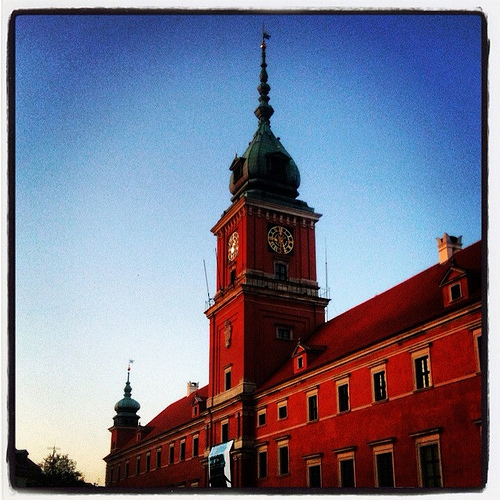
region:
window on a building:
[414, 435, 446, 487]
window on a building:
[373, 442, 398, 487]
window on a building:
[336, 450, 352, 492]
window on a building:
[306, 456, 318, 491]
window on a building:
[276, 436, 291, 475]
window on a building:
[257, 444, 271, 480]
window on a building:
[253, 405, 268, 425]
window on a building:
[276, 401, 290, 419]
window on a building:
[303, 385, 319, 420]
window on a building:
[332, 374, 355, 411]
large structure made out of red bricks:
[91, 26, 499, 496]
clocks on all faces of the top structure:
[213, 214, 320, 279]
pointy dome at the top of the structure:
[213, 21, 311, 209]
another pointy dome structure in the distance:
[108, 353, 146, 433]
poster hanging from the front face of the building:
[198, 436, 243, 492]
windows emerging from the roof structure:
[129, 269, 478, 446]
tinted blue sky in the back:
[3, 10, 485, 387]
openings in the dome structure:
[223, 153, 295, 185]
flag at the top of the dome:
[252, 23, 277, 55]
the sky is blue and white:
[41, 269, 188, 331]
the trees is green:
[42, 449, 84, 476]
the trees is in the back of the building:
[44, 435, 94, 485]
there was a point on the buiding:
[117, 343, 137, 409]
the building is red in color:
[155, 350, 412, 430]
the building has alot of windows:
[279, 362, 458, 397]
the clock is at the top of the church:
[264, 223, 308, 254]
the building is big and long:
[156, 382, 456, 467]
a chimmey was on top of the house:
[434, 241, 469, 263]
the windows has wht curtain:
[416, 362, 428, 389]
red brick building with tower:
[97, 20, 487, 485]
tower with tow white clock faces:
[200, 15, 327, 397]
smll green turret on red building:
[109, 357, 150, 440]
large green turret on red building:
[225, 20, 300, 196]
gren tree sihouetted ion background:
[38, 443, 87, 488]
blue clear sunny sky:
[30, 22, 480, 459]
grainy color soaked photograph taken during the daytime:
[20, 15, 485, 482]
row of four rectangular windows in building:
[304, 428, 452, 491]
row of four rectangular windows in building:
[290, 343, 449, 430]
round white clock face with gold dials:
[265, 219, 300, 258]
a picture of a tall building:
[159, 155, 429, 462]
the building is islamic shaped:
[76, 74, 466, 481]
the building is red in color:
[148, 362, 370, 497]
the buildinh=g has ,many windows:
[127, 360, 419, 472]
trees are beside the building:
[23, 416, 100, 498]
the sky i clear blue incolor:
[81, 72, 157, 199]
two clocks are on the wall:
[191, 216, 318, 290]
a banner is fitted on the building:
[199, 429, 241, 499]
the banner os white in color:
[192, 439, 240, 497]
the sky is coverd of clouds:
[36, 349, 115, 464]